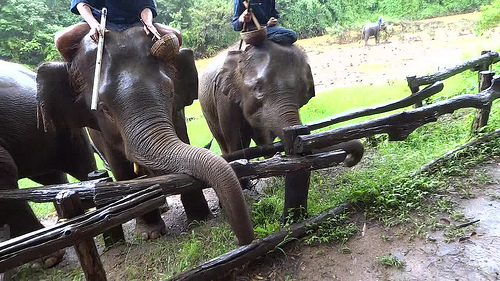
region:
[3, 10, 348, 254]
people on the elephants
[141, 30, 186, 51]
bowl in person's hand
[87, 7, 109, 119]
rod in person's hand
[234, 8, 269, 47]
bowl and rod in person's hands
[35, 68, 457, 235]
fence made of wood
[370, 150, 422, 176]
plants near the fence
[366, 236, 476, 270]
bare ground near the fence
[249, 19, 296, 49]
pants on the person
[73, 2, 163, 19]
shirt on the person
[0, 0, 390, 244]
several elephants with people on them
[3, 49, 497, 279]
wooden fence made of logs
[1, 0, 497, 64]
green trees in the landscape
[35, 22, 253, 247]
elephant's trunk is over the fence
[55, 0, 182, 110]
elephant rider is holding a stick and bowl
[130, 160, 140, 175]
small ivory elephant tusk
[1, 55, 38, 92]
sun shining on elephant's back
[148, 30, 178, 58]
small round wicker basket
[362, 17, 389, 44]
person in blue is on elephant's back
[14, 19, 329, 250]
two elephants standing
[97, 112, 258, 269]
large curved elephant trunk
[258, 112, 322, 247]
large curved elephant trunk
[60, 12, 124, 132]
wooden pole in hand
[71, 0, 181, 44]
person on top of elephant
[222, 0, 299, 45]
person on top of animal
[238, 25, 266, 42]
brown bucket in had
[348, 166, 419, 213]
green grass on bottom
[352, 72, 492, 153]
old wooden fence post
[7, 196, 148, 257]
brown wooden fence post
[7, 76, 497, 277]
the fence is wooden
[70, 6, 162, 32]
person on the elephant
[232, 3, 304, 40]
person on the elephant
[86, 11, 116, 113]
person holding the stick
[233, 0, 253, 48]
person holding the stick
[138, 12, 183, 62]
person holding the bowl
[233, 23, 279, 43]
person holding the bowl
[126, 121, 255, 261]
trunk of the elephant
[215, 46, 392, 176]
head of the elephant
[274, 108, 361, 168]
the truck of an elephant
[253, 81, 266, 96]
eye of an elephant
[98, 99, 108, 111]
eye of an elephant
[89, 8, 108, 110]
a thin wooden stick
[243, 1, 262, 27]
a thin wooden stick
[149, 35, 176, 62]
a woven brown bucket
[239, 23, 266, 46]
a woven brown bucket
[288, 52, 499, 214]
a thick wooden fence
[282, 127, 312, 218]
a thick wooden post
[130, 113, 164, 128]
wrinkle on elephant trunk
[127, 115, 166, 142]
wrinkle on elephant trunk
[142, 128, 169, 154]
wrinkle on elephant trunk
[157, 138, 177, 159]
wrinkle on elephant trunk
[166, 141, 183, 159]
wrinkle on elephant trunk